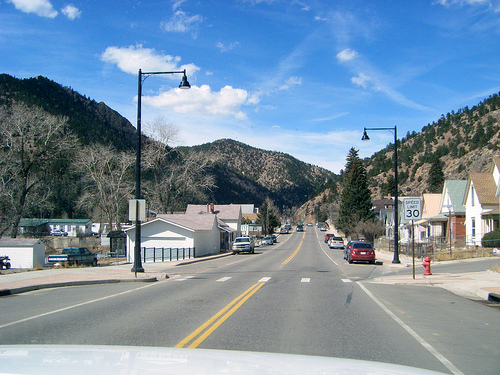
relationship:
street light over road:
[132, 70, 192, 273] [0, 226, 499, 374]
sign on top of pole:
[403, 198, 422, 221] [412, 221, 417, 280]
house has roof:
[122, 212, 220, 260] [122, 215, 217, 232]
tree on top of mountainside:
[426, 157, 446, 190] [287, 90, 500, 225]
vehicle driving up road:
[296, 223, 304, 233] [0, 226, 499, 374]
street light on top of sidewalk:
[132, 70, 192, 273] [0, 226, 286, 297]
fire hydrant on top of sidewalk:
[421, 256, 432, 276] [325, 219, 500, 305]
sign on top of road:
[403, 198, 422, 221] [0, 226, 499, 374]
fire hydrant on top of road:
[421, 256, 432, 276] [0, 226, 499, 374]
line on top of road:
[175, 276, 272, 347] [0, 226, 499, 374]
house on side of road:
[122, 212, 220, 260] [0, 226, 499, 374]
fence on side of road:
[137, 247, 196, 262] [0, 226, 499, 374]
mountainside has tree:
[287, 90, 500, 225] [426, 157, 446, 190]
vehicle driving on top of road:
[296, 223, 304, 233] [0, 226, 499, 374]